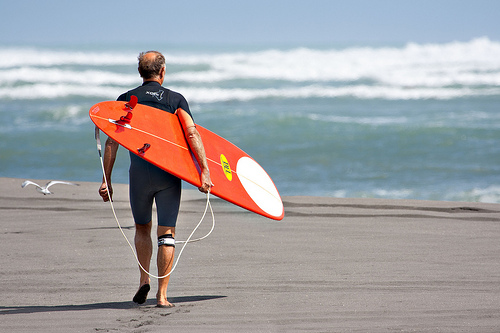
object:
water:
[311, 33, 500, 195]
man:
[96, 49, 214, 308]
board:
[89, 94, 285, 221]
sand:
[318, 205, 500, 333]